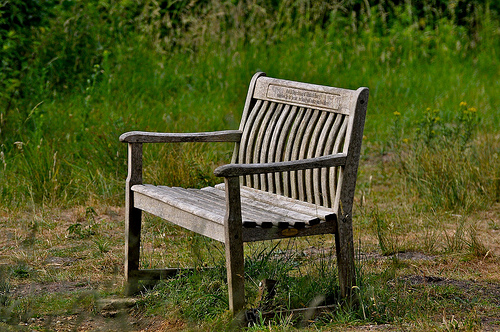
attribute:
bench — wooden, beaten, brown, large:
[101, 68, 377, 307]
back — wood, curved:
[244, 71, 365, 146]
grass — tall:
[400, 70, 498, 211]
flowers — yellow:
[390, 102, 495, 140]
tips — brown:
[187, 5, 326, 24]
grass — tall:
[120, 10, 487, 99]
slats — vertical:
[258, 108, 265, 170]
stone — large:
[105, 291, 138, 309]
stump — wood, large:
[261, 285, 327, 319]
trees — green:
[146, 14, 465, 55]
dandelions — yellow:
[394, 101, 488, 123]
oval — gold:
[281, 227, 302, 238]